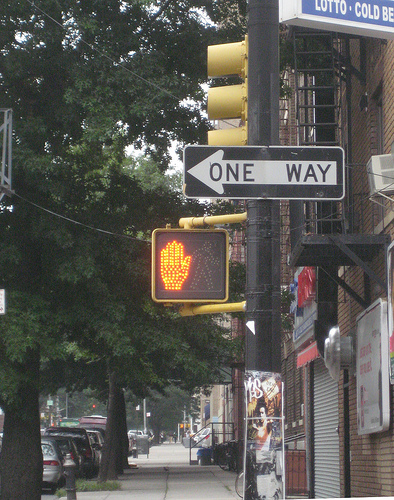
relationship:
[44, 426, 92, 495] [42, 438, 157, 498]
car parked along curb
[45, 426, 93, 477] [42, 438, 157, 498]
car parked along curb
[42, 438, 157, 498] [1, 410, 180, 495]
curb on street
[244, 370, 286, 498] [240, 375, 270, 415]
poster with graffiti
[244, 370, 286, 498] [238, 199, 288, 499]
poster on pole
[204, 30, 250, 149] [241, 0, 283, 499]
lights on black pole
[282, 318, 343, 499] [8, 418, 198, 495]
garage door on street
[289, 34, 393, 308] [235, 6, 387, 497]
fire escape outside of building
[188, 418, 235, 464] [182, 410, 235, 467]
rail on steps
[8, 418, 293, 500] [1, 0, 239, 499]
street between trees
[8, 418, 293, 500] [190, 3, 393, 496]
street between buildings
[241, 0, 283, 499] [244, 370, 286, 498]
black pole with poster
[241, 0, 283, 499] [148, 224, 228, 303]
black pole with traffic lights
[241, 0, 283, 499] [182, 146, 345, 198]
black pole with traffic sign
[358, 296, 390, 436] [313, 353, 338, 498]
sign near metal gate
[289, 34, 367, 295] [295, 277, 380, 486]
fire escape on building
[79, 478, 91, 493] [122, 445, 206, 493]
grass growing on sidewalk